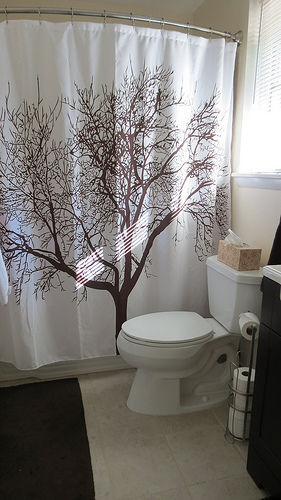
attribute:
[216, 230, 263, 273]
kleenex box — tan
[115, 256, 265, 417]
toilet — white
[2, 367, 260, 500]
floor — white, tiled, beige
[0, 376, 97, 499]
rug — brown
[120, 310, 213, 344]
lid — white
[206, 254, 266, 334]
tank — white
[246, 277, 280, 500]
cupboard — black, brown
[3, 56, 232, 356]
tree — brown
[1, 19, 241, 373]
shower curtain — white, hanging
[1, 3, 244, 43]
rod — curved, silver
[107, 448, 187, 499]
tile — white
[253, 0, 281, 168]
blinds — white